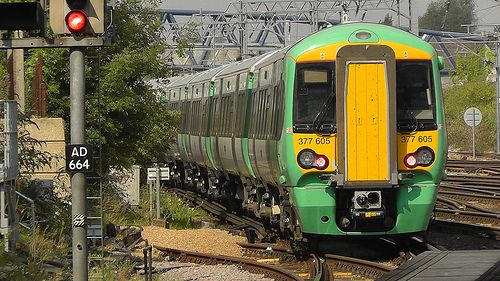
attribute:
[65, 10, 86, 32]
light — red, circular, lit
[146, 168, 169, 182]
sign — rectangular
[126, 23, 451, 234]
train — driving, yellow, green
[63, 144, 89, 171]
sign — small, black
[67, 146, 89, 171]
writing — ad644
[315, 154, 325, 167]
headlight — illuminated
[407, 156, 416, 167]
headlight — illuminated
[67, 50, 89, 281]
pole — metal, grey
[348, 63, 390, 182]
door — yellow